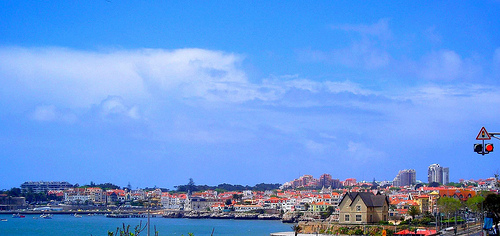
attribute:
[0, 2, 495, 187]
sky — blue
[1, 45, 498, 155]
clouds — white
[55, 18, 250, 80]
clouds — white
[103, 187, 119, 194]
roof — red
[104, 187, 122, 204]
building — old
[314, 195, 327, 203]
roof — red 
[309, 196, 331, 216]
building — old 